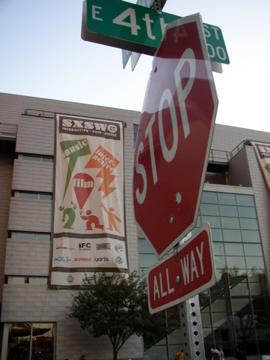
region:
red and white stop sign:
[130, 11, 221, 263]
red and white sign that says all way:
[142, 220, 218, 314]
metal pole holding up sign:
[174, 288, 209, 359]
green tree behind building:
[73, 264, 162, 354]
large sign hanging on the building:
[49, 110, 136, 304]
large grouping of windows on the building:
[131, 176, 267, 358]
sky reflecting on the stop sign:
[137, 50, 226, 115]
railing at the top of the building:
[19, 102, 266, 173]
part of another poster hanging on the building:
[241, 135, 268, 208]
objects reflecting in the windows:
[131, 264, 261, 357]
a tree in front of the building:
[45, 253, 151, 359]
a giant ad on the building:
[63, 106, 142, 295]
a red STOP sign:
[124, 40, 233, 230]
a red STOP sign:
[112, 82, 233, 311]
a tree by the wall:
[69, 267, 131, 358]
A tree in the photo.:
[76, 287, 138, 344]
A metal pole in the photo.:
[181, 310, 213, 357]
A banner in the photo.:
[50, 111, 128, 284]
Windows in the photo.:
[9, 274, 33, 286]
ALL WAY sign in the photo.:
[142, 264, 221, 310]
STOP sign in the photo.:
[134, 25, 220, 238]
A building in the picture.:
[11, 98, 50, 145]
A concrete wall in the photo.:
[14, 292, 60, 315]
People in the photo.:
[208, 343, 225, 359]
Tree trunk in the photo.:
[109, 347, 120, 359]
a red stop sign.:
[125, 8, 223, 254]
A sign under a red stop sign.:
[139, 224, 226, 318]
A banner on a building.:
[45, 99, 138, 294]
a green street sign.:
[73, 0, 245, 78]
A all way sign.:
[138, 222, 229, 320]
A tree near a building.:
[58, 248, 164, 358]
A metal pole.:
[167, 223, 212, 358]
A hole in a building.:
[12, 268, 38, 294]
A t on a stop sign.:
[140, 110, 166, 189]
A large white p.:
[171, 51, 201, 141]